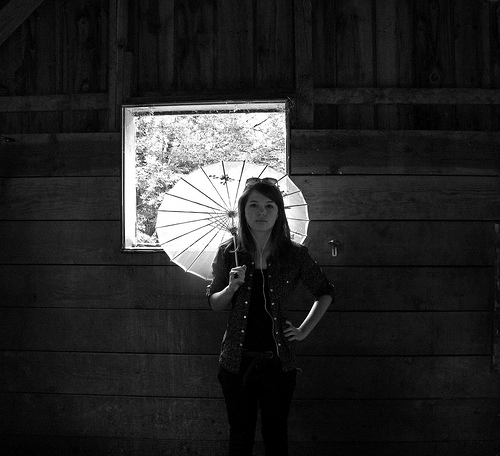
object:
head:
[237, 179, 283, 232]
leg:
[257, 354, 296, 456]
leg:
[215, 353, 260, 456]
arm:
[301, 249, 338, 335]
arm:
[204, 243, 232, 312]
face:
[244, 189, 279, 232]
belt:
[241, 351, 278, 359]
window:
[120, 98, 290, 255]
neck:
[247, 226, 272, 247]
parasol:
[152, 159, 313, 285]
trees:
[135, 110, 284, 246]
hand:
[226, 262, 249, 294]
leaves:
[138, 133, 141, 135]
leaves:
[196, 138, 200, 143]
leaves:
[147, 163, 153, 166]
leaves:
[205, 150, 209, 156]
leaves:
[139, 131, 144, 134]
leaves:
[227, 137, 232, 143]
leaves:
[143, 191, 145, 194]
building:
[0, 0, 499, 456]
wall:
[0, 133, 499, 456]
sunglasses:
[244, 177, 279, 188]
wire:
[260, 229, 280, 354]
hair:
[235, 174, 291, 259]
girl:
[205, 178, 335, 456]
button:
[271, 302, 275, 305]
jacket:
[202, 230, 336, 376]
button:
[277, 343, 281, 347]